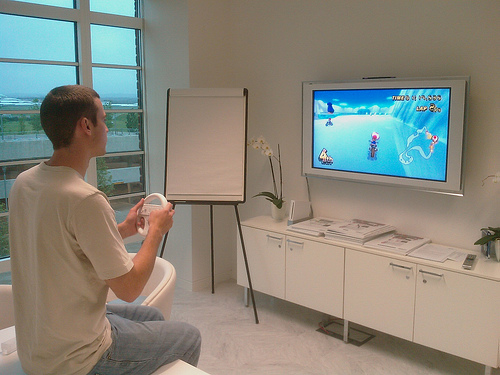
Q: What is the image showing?
A: It is showing an office.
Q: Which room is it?
A: It is an office.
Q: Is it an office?
A: Yes, it is an office.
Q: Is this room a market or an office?
A: It is an office.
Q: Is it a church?
A: No, it is an office.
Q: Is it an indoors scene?
A: Yes, it is indoors.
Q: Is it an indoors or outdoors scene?
A: It is indoors.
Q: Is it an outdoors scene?
A: No, it is indoors.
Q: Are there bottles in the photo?
A: No, there are no bottles.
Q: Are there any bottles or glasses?
A: No, there are no bottles or glasses.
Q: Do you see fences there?
A: No, there are no fences.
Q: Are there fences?
A: No, there are no fences.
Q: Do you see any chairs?
A: Yes, there is a chair.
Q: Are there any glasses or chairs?
A: Yes, there is a chair.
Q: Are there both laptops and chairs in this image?
A: No, there is a chair but no laptops.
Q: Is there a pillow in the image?
A: No, there are no pillows.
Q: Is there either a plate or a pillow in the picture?
A: No, there are no pillows or plates.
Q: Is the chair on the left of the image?
A: Yes, the chair is on the left of the image.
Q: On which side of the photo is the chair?
A: The chair is on the left of the image.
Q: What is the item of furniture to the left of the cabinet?
A: The piece of furniture is a chair.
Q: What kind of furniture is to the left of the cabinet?
A: The piece of furniture is a chair.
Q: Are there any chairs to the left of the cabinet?
A: Yes, there is a chair to the left of the cabinet.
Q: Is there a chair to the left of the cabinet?
A: Yes, there is a chair to the left of the cabinet.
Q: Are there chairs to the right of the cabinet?
A: No, the chair is to the left of the cabinet.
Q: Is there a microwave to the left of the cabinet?
A: No, there is a chair to the left of the cabinet.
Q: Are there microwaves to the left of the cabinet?
A: No, there is a chair to the left of the cabinet.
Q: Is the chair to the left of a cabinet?
A: Yes, the chair is to the left of a cabinet.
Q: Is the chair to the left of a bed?
A: No, the chair is to the left of a cabinet.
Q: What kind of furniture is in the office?
A: The piece of furniture is a chair.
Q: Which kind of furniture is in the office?
A: The piece of furniture is a chair.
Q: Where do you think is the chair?
A: The chair is in the office.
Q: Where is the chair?
A: The chair is in the office.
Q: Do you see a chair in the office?
A: Yes, there is a chair in the office.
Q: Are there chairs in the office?
A: Yes, there is a chair in the office.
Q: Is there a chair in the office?
A: Yes, there is a chair in the office.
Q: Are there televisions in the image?
A: Yes, there is a television.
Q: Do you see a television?
A: Yes, there is a television.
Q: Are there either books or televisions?
A: Yes, there is a television.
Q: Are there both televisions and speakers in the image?
A: No, there is a television but no speakers.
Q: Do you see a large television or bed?
A: Yes, there is a large television.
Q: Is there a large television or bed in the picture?
A: Yes, there is a large television.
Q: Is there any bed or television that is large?
A: Yes, the television is large.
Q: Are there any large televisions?
A: Yes, there is a large television.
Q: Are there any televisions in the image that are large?
A: Yes, there is a television that is large.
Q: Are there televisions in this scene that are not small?
A: Yes, there is a large television.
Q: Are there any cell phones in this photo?
A: No, there are no cell phones.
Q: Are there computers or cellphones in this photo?
A: No, there are no cellphones or computers.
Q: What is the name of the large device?
A: The device is a television.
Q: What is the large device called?
A: The device is a television.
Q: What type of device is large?
A: The device is a television.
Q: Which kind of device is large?
A: The device is a television.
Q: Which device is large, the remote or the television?
A: The television is large.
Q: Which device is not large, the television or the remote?
A: The remote is not large.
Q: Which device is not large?
A: The device is a remote control.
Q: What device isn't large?
A: The device is a remote control.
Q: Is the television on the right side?
A: Yes, the television is on the right of the image.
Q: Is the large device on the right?
A: Yes, the television is on the right of the image.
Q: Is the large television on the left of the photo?
A: No, the TV is on the right of the image.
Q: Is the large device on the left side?
A: No, the TV is on the right of the image.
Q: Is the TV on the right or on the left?
A: The TV is on the right of the image.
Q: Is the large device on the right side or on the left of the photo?
A: The TV is on the right of the image.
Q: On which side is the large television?
A: The television is on the right of the image.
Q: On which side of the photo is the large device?
A: The television is on the right of the image.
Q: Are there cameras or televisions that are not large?
A: No, there is a television but it is large.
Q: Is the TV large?
A: Yes, the TV is large.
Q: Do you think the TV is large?
A: Yes, the TV is large.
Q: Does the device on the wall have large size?
A: Yes, the TV is large.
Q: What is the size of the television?
A: The television is large.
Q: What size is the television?
A: The television is large.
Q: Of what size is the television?
A: The television is large.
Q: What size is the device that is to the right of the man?
A: The television is large.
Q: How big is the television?
A: The television is large.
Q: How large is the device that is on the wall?
A: The television is large.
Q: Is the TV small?
A: No, the TV is large.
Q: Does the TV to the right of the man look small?
A: No, the television is large.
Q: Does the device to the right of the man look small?
A: No, the television is large.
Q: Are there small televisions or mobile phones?
A: No, there is a television but it is large.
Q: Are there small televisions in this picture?
A: No, there is a television but it is large.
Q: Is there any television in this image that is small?
A: No, there is a television but it is large.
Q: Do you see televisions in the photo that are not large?
A: No, there is a television but it is large.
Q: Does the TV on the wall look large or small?
A: The TV is large.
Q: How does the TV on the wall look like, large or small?
A: The TV is large.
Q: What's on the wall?
A: The TV is on the wall.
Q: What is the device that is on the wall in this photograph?
A: The device is a television.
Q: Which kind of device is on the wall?
A: The device is a television.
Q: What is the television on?
A: The television is on the wall.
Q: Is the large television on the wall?
A: Yes, the TV is on the wall.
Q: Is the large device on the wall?
A: Yes, the TV is on the wall.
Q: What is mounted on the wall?
A: The television is mounted on the wall.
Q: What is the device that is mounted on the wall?
A: The device is a television.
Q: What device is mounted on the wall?
A: The device is a television.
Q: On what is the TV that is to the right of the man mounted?
A: The TV is mounted on the wall.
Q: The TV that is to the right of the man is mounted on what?
A: The TV is mounted on the wall.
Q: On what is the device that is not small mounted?
A: The TV is mounted on the wall.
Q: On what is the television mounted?
A: The TV is mounted on the wall.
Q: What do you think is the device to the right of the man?
A: The device is a television.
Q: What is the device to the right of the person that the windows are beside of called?
A: The device is a television.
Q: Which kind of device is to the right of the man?
A: The device is a television.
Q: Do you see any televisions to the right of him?
A: Yes, there is a television to the right of the man.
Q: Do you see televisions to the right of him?
A: Yes, there is a television to the right of the man.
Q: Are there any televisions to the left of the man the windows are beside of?
A: No, the television is to the right of the man.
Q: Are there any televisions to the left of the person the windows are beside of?
A: No, the television is to the right of the man.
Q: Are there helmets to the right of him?
A: No, there is a television to the right of the man.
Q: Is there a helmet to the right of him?
A: No, there is a television to the right of the man.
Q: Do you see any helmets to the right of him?
A: No, there is a television to the right of the man.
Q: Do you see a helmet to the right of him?
A: No, there is a television to the right of the man.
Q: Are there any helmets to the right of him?
A: No, there is a television to the right of the man.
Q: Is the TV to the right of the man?
A: Yes, the TV is to the right of the man.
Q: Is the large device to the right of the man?
A: Yes, the TV is to the right of the man.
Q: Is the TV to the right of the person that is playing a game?
A: Yes, the TV is to the right of the man.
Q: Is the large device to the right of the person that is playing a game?
A: Yes, the TV is to the right of the man.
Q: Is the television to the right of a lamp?
A: No, the television is to the right of the man.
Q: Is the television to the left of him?
A: No, the television is to the right of the man.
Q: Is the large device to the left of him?
A: No, the television is to the right of the man.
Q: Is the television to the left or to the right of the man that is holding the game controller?
A: The television is to the right of the man.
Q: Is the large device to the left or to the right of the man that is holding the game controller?
A: The television is to the right of the man.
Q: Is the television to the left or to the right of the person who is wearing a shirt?
A: The television is to the right of the man.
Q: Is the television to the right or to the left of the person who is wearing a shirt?
A: The television is to the right of the man.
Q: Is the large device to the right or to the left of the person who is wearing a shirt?
A: The television is to the right of the man.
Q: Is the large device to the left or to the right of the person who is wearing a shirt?
A: The television is to the right of the man.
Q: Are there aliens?
A: No, there are no aliens.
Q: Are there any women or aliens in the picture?
A: No, there are no aliens or women.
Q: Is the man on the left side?
A: Yes, the man is on the left of the image.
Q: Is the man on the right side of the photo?
A: No, the man is on the left of the image.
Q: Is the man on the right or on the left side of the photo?
A: The man is on the left of the image.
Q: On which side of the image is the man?
A: The man is on the left of the image.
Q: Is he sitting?
A: Yes, the man is sitting.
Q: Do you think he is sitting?
A: Yes, the man is sitting.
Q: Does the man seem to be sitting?
A: Yes, the man is sitting.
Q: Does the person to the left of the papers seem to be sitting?
A: Yes, the man is sitting.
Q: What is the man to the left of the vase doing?
A: The man is sitting.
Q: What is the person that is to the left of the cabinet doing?
A: The man is sitting.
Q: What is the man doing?
A: The man is sitting.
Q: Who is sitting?
A: The man is sitting.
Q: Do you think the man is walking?
A: No, the man is sitting.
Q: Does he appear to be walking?
A: No, the man is sitting.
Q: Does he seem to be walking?
A: No, the man is sitting.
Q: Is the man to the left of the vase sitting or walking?
A: The man is sitting.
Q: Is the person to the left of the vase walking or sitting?
A: The man is sitting.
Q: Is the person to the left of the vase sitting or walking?
A: The man is sitting.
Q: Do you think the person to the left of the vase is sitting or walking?
A: The man is sitting.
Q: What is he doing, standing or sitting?
A: The man is sitting.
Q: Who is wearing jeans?
A: The man is wearing jeans.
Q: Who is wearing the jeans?
A: The man is wearing jeans.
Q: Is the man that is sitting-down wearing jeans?
A: Yes, the man is wearing jeans.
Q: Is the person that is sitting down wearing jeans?
A: Yes, the man is wearing jeans.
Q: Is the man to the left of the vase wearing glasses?
A: No, the man is wearing jeans.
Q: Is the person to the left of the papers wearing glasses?
A: No, the man is wearing jeans.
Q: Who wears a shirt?
A: The man wears a shirt.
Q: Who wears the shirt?
A: The man wears a shirt.